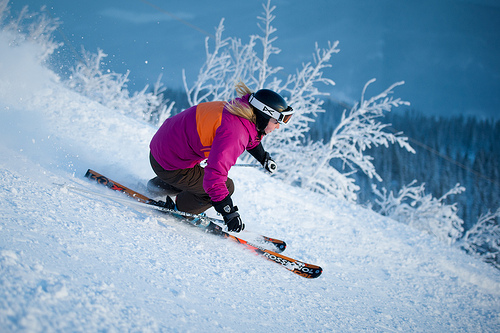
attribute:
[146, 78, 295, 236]
woman — skiing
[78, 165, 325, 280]
ski — colorful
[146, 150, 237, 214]
pants — brown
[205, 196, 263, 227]
glove — black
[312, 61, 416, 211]
tree — snow covered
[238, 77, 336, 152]
helmet — black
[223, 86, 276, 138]
hair — blonde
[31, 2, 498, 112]
sky — blue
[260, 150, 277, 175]
glove — black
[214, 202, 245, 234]
glove — black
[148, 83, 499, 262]
mountain — snowy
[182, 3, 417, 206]
tree limb — snow covered